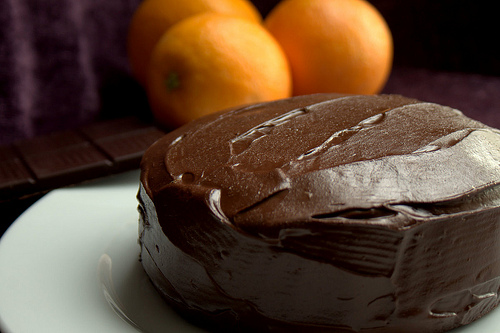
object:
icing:
[137, 92, 499, 333]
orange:
[146, 9, 289, 127]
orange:
[128, 0, 265, 83]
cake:
[135, 90, 500, 333]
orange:
[264, 0, 394, 99]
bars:
[5, 112, 172, 195]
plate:
[0, 161, 500, 333]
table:
[0, 0, 500, 333]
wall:
[172, 83, 227, 129]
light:
[98, 245, 125, 319]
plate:
[100, 213, 148, 330]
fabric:
[0, 0, 139, 140]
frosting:
[306, 107, 498, 209]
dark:
[235, 133, 442, 261]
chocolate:
[235, 107, 452, 177]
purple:
[6, 44, 38, 133]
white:
[0, 200, 134, 333]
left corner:
[0, 165, 100, 193]